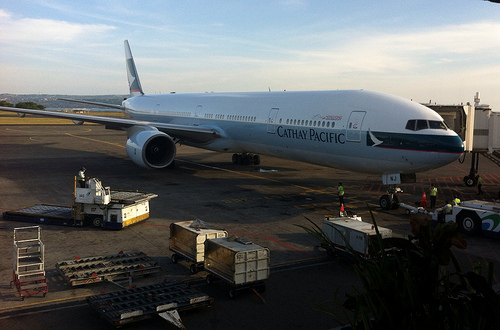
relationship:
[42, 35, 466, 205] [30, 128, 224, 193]
plane on tarmac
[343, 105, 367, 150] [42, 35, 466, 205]
door on plane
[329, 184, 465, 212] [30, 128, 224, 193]
workers on tarmac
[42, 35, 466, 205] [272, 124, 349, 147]
plane has name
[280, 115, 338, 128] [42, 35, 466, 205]
windows on plane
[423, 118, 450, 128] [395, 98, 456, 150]
windshield on cockpit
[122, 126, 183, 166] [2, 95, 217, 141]
engine on wing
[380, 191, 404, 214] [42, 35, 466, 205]
wheels on plane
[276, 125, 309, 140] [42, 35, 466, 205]
cathay on plane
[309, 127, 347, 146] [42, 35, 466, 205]
pacific on plane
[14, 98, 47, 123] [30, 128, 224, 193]
tree in tarmac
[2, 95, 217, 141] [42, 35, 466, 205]
wing on plane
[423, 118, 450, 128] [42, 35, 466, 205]
windshield on plane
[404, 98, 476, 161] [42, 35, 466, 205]
front of plane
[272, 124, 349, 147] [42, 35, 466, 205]
name of plane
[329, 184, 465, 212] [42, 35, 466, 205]
workers of plane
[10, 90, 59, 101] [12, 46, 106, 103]
hills i background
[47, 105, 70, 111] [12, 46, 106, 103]
water in background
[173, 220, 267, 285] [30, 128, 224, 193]
crates on tarmac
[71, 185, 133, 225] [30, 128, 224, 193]
vehicle on tarmac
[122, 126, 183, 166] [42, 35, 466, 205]
engine on plane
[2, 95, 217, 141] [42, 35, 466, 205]
wing of plane